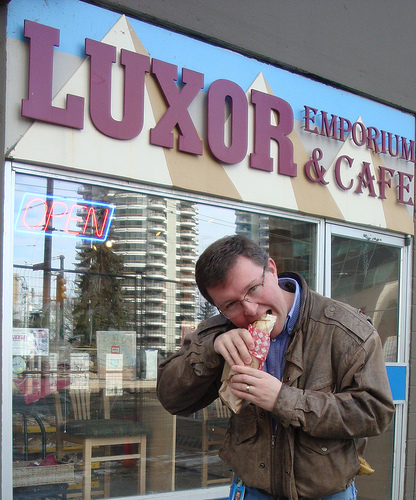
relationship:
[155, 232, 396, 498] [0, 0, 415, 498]
man in front of cafe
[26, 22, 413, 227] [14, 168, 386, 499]
sign for cafe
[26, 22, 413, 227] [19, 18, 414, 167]
sign for luxor emporium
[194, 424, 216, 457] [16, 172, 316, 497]
chair in window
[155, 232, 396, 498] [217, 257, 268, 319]
man wearing glasses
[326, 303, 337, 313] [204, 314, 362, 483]
button on jacket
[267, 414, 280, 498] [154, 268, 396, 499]
zipper on jacket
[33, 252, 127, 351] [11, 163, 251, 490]
reflections in mirror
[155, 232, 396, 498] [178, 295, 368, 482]
man wearing jacket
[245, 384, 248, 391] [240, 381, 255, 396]
gold band on finger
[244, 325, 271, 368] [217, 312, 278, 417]
wrapping on pita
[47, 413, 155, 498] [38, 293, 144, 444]
chair behind window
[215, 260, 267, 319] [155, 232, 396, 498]
glasses on man